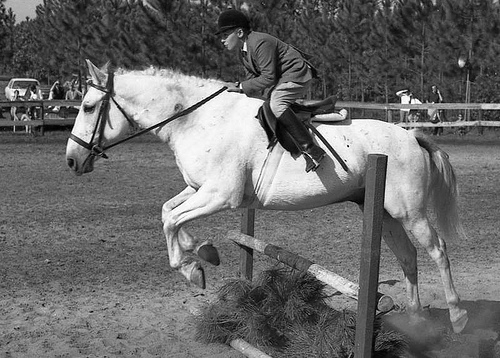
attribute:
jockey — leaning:
[186, 16, 392, 193]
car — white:
[6, 78, 41, 97]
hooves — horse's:
[399, 302, 476, 337]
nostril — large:
[65, 154, 77, 171]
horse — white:
[39, 65, 482, 337]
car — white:
[3, 71, 41, 101]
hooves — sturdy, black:
[188, 242, 222, 292]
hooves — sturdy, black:
[403, 310, 467, 335]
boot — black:
[276, 107, 324, 177]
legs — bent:
[151, 187, 265, 307]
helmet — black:
[211, 6, 253, 33]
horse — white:
[62, 53, 483, 317]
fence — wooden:
[224, 145, 406, 356]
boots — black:
[289, 131, 327, 171]